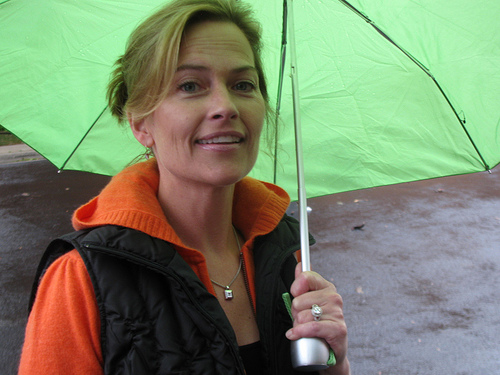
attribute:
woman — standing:
[11, 0, 354, 375]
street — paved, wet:
[2, 164, 499, 375]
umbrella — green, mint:
[0, 0, 497, 205]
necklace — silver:
[181, 219, 255, 307]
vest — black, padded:
[30, 209, 324, 374]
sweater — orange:
[20, 165, 292, 373]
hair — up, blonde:
[105, 5, 282, 144]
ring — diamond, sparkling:
[311, 305, 323, 320]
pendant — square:
[223, 288, 232, 300]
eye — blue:
[182, 83, 199, 93]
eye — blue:
[235, 80, 255, 93]